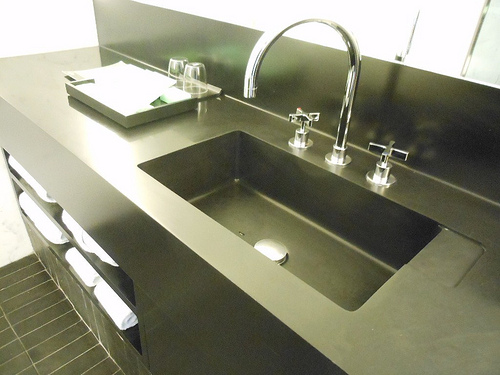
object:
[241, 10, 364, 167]
faucet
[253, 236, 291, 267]
drain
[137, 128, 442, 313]
sink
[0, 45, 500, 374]
counter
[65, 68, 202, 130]
tray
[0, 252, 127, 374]
floor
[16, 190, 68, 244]
towel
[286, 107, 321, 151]
handle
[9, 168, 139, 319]
shelves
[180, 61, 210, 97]
glass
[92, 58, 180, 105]
napkin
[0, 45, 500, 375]
table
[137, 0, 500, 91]
mirror